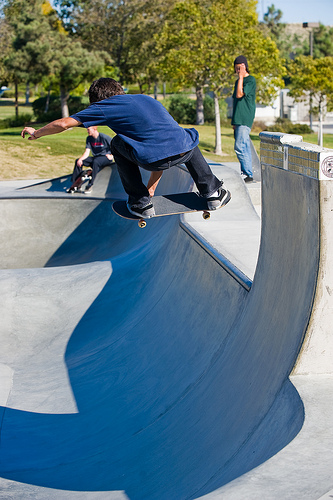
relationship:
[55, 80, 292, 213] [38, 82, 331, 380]
kids at park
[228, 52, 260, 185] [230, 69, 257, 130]
boy wearing shirt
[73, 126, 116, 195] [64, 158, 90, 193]
man with skateboard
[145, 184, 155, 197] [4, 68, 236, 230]
hand of guy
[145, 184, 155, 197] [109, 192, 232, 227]
hand on skateboard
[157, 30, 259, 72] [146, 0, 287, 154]
leaves on tree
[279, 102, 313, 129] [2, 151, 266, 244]
trash near walkway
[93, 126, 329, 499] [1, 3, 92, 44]
walls of park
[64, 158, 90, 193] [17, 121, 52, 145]
skateboard has hand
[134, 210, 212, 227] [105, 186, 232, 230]
wheels of skateboard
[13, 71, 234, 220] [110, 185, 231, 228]
boy on side of skateboard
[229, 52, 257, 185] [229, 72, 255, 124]
boy wears shirt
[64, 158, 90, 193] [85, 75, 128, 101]
skateboard has hair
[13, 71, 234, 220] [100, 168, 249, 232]
boy on skateboard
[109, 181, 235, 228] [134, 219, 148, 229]
skateboard has wheel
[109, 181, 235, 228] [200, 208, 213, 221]
skateboard has wheel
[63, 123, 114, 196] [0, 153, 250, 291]
boy sitting on rink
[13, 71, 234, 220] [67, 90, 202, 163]
boy wearing shirt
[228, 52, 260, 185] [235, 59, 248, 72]
boy covering face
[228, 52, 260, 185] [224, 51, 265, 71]
boy wearing hat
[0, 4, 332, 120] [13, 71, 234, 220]
trees behind boy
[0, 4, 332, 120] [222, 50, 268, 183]
trees behind boy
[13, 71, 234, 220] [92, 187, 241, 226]
boy riding skateboard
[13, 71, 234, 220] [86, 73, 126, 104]
boy with hair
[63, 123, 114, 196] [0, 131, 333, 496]
boy sitting on ramp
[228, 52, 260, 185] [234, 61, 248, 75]
boy with hand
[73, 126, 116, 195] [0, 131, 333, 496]
man sitting on ramp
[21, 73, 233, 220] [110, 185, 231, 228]
skateboarder holding skateboard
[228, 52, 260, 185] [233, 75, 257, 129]
boy wearing shirt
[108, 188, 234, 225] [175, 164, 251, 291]
skater balancing on edge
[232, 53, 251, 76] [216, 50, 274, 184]
head of boy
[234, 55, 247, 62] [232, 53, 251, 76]
beanie on head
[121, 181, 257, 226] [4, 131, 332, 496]
skateboard on top of skateboard ramp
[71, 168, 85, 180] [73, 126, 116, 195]
foot of man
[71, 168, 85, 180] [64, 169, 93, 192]
foot on skateboard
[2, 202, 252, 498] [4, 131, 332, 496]
shadow on skateboard ramp